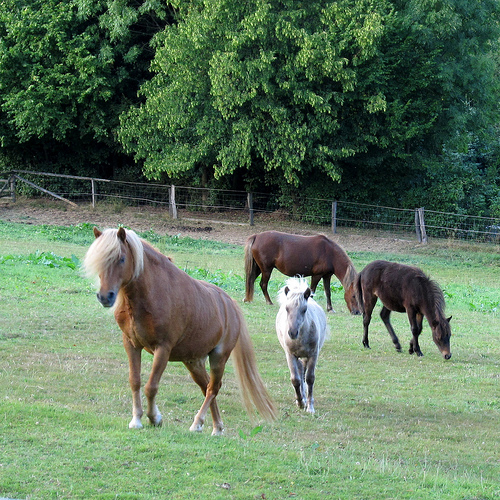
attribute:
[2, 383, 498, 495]
hill — small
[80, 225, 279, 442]
brown horse — light brown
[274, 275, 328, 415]
horse — white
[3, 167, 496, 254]
fence — low, wire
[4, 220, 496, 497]
grass — green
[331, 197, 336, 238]
fence post — wooden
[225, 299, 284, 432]
tail — blonde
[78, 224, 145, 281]
hair — blonde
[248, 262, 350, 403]
horse — white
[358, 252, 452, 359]
horse — brown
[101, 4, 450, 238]
trees — thick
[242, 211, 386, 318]
horse — brown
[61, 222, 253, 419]
horse — light brown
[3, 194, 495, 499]
field — grassy, green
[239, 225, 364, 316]
horse — brown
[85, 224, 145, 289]
mane — blonde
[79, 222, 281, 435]
horse — tan, light brown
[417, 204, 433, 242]
poles — wood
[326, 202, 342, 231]
poles — wood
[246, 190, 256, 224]
poles — wood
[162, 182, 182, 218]
poles — wood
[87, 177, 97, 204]
poles — wood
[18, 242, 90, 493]
field — grassy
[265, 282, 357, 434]
horse — white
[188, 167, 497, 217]
bush — thick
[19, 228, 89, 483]
field — grassy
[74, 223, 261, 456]
horse — light brown